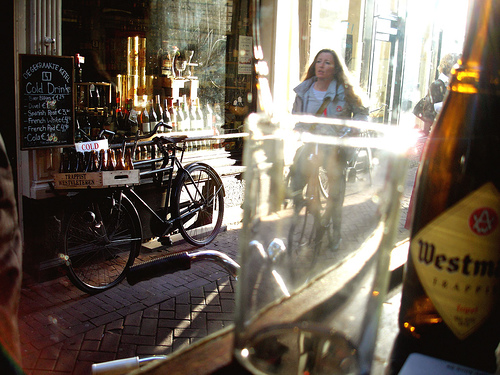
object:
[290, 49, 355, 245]
woman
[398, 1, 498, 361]
bottle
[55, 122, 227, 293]
bike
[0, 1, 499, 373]
bar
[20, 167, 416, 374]
sidewalk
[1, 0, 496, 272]
building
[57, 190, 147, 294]
tire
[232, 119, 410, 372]
glass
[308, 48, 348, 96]
hair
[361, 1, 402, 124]
entrance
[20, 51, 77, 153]
sign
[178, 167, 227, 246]
wheel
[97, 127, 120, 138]
handle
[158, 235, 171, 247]
pedal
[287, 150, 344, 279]
bike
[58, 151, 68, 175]
bottle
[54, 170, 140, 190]
basket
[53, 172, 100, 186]
logo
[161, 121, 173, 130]
handle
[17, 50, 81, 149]
chalkboard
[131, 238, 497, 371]
table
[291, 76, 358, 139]
jacket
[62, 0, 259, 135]
window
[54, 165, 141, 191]
crate